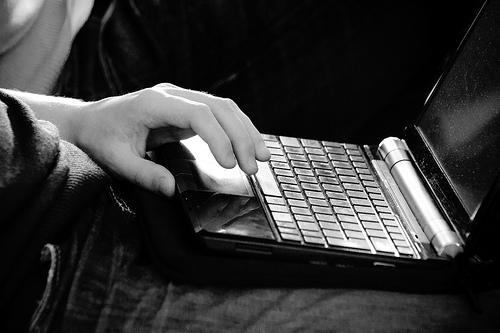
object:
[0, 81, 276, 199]
hand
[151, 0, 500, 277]
laptop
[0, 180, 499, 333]
pants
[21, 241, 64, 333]
pocket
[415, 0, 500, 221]
screen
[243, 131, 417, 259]
keyboard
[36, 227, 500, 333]
lap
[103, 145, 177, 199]
thumb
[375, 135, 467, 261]
hinge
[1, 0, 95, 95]
cloth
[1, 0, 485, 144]
background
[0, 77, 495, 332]
man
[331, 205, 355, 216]
keys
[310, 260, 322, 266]
ports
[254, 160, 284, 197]
space bar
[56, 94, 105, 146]
wrist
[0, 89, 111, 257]
stomach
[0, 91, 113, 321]
sweater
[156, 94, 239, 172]
fingers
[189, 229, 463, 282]
edge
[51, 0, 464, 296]
bag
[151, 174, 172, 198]
nails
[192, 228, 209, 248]
corner